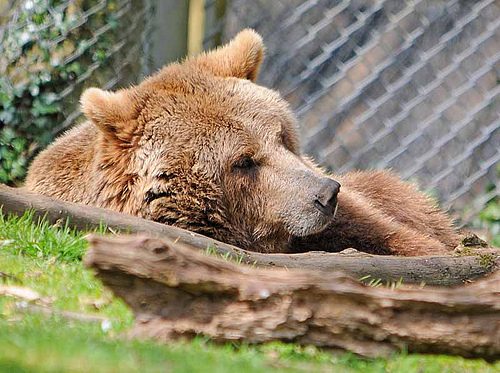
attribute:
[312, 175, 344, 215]
nose — black, bears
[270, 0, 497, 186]
fence — chain link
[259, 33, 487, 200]
fence — grey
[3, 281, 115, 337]
sand — brown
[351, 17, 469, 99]
fence — metallic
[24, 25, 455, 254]
bear — brown, large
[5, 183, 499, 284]
branch — tree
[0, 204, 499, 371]
grass — short, green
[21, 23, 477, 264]
bear — brown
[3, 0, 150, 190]
bush — green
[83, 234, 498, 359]
wood — pieces, piece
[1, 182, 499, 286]
wood — piece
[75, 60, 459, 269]
bear — round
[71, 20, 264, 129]
ears — small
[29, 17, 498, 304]
bear — on its side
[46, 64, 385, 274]
bear — brown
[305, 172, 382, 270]
nose — black